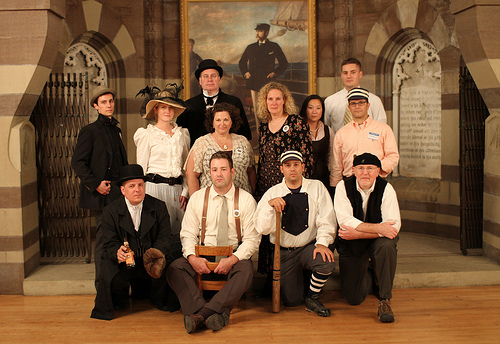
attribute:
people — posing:
[69, 60, 402, 330]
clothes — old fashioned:
[72, 91, 400, 328]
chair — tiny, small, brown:
[193, 244, 233, 302]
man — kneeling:
[253, 150, 331, 318]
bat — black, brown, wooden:
[271, 205, 282, 313]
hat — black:
[194, 60, 223, 79]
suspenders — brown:
[200, 187, 241, 247]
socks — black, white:
[307, 269, 330, 298]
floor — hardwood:
[1, 288, 499, 343]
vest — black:
[339, 174, 385, 223]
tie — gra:
[342, 106, 350, 125]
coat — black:
[91, 197, 177, 316]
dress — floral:
[257, 113, 314, 186]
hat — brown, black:
[141, 90, 185, 118]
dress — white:
[133, 123, 189, 224]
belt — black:
[145, 174, 182, 188]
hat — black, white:
[345, 89, 367, 99]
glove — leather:
[142, 246, 164, 279]